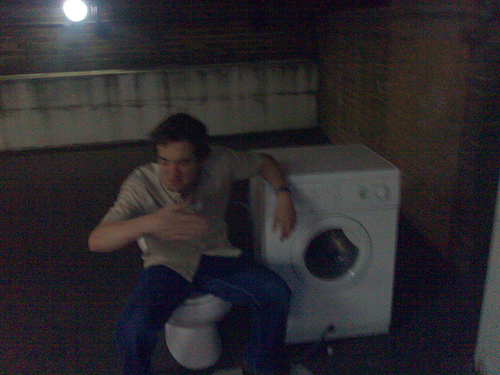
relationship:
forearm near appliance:
[259, 156, 292, 196] [246, 141, 406, 340]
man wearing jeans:
[87, 110, 301, 375] [112, 251, 296, 375]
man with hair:
[87, 110, 301, 375] [149, 112, 210, 160]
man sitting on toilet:
[87, 110, 301, 375] [165, 286, 236, 370]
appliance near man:
[246, 141, 406, 340] [87, 110, 301, 375]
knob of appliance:
[374, 185, 390, 200] [246, 141, 406, 340]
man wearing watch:
[87, 110, 301, 375] [273, 183, 292, 197]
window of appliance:
[303, 229, 357, 278] [246, 141, 406, 340]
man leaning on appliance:
[87, 110, 301, 375] [246, 141, 406, 340]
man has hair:
[87, 110, 301, 375] [149, 112, 210, 160]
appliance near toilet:
[246, 141, 406, 340] [165, 286, 236, 370]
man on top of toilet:
[87, 110, 301, 375] [165, 286, 236, 370]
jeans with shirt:
[112, 251, 296, 375] [97, 144, 266, 284]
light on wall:
[61, 1, 92, 24] [60, 0, 90, 24]